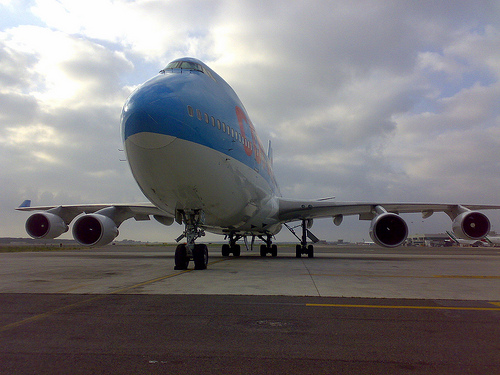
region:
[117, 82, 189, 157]
shiny blue airplane nose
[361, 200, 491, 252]
two round airplane engines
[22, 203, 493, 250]
front of four airplane engines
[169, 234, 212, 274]
two black airplane wheels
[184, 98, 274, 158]
several rectangular airplane windows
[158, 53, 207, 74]
two front airplane windows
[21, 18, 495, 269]
large plane with white clouds in background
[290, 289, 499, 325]
yellow stripe on airport runway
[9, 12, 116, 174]
white clouds with sunlight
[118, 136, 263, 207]
underbelly of large airplane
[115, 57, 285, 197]
Blue painted jet airplane.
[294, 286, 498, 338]
Yellow markings on an airfield.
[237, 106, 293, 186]
Red writing on side of plane.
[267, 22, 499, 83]
Puffy gray and white clouds.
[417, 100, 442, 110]
Blue sky playing peek a boo in the sky.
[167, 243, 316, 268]
Four sets of wheels on a plane.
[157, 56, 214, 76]
The cockpit of airplane.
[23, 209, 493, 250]
Four jet engines on a large planes.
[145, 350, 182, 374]
Small pool of water on an airfield.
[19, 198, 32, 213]
Blue tip on an airplane's wing.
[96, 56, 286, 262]
white and blue airplane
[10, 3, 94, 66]
white clouds in blue sky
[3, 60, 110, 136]
white clouds in blue sky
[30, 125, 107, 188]
white clouds in blue sky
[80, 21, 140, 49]
white clouds in blue sky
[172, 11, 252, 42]
white clouds in blue sky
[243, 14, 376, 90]
white clouds in blue sky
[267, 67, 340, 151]
white clouds in blue sky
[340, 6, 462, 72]
white clouds in blue sky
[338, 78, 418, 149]
white clouds in blue sky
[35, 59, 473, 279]
blue and white airplane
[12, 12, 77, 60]
white clouds in blue sky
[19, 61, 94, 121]
white clouds in blue sky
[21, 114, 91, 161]
white clouds in blue sky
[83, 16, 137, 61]
white clouds in blue sky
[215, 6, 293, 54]
white clouds in blue sky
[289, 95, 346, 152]
white clouds in blue sky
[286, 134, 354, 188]
white clouds in blue sky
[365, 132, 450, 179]
white clouds in blue sky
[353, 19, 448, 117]
white clouds in blue sky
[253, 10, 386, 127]
Thick white clouds in the sky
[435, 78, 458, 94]
A small patch of clear blue sky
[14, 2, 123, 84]
The sun is shining intensely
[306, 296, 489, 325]
A yellow line on the runway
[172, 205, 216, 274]
The front landing gear of the airplane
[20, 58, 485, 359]
A large airplane on a runway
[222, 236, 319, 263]
The rear landing gears of the plane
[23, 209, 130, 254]
The two right engines of the plane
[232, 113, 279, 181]
Red letters on the large aircraft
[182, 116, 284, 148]
Small windows line the plane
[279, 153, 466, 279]
wing of the plane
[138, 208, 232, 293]
wheel of the plane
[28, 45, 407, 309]
blue and white plane